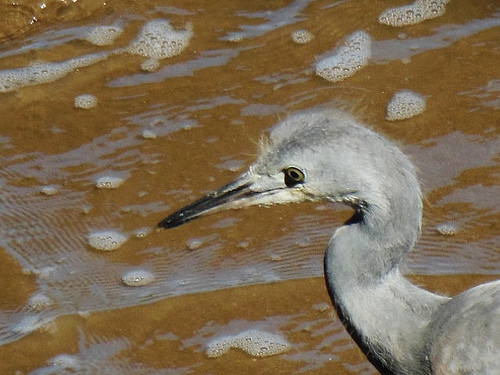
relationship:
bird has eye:
[155, 102, 499, 372] [281, 165, 310, 185]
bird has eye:
[155, 102, 499, 372] [283, 165, 305, 186]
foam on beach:
[211, 331, 287, 352] [86, 251, 151, 323]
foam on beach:
[87, 218, 148, 265] [107, 291, 182, 339]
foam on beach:
[31, 162, 126, 201] [41, 224, 125, 309]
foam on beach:
[117, 29, 184, 60] [85, 76, 135, 116]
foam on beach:
[125, 25, 197, 72] [106, 81, 162, 137]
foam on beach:
[123, 12, 186, 61] [174, 50, 252, 104]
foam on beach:
[367, 71, 438, 139] [97, 119, 173, 164]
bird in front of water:
[225, 76, 433, 366] [39, 168, 165, 324]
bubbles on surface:
[65, 141, 121, 279] [37, 170, 151, 312]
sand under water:
[64, 159, 106, 240] [87, 256, 195, 331]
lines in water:
[18, 230, 108, 317] [161, 305, 204, 329]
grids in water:
[50, 242, 150, 305] [161, 305, 204, 329]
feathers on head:
[275, 91, 410, 230] [229, 110, 407, 255]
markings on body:
[383, 289, 478, 365] [313, 209, 498, 366]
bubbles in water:
[127, 29, 184, 54] [139, 56, 190, 108]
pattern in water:
[17, 209, 120, 296] [93, 299, 177, 343]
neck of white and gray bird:
[325, 197, 430, 355] [145, 90, 493, 364]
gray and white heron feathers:
[437, 306, 456, 322] [376, 278, 496, 352]